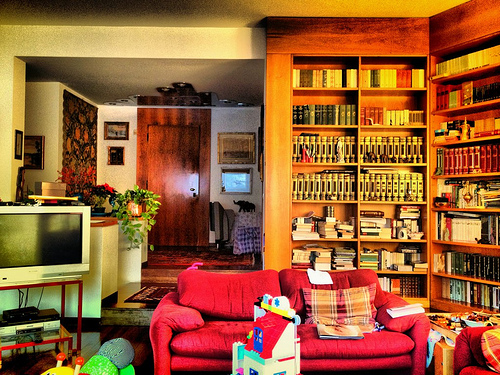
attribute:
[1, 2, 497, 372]
home — cluttered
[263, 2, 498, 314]
bookcase — wooden, large, full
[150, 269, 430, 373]
sofa — red, plush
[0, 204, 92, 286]
television — white, small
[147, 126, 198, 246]
door — wooden, closed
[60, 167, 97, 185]
flowers — red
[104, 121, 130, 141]
picture — framed, hanging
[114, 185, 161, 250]
plant — hanging, green, growing, ivy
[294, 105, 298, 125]
book — reference, many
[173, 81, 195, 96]
panel — mirrored, decorative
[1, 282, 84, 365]
stand — red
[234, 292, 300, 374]
toy — house, blocks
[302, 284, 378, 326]
pillow — red, plaid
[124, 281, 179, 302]
rug — printed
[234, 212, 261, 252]
tablecloth — plaid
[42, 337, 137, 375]
toy — worm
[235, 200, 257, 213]
elephant — small